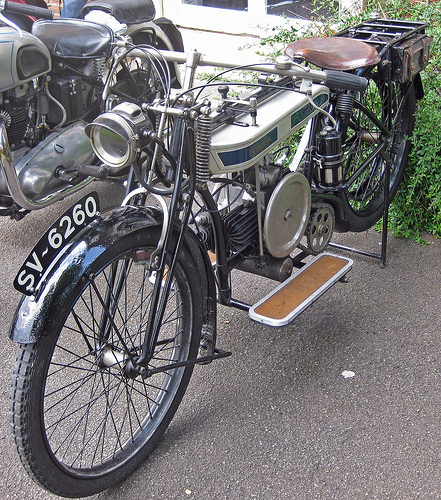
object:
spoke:
[100, 262, 140, 357]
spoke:
[47, 357, 120, 378]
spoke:
[122, 371, 136, 449]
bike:
[0, 0, 187, 223]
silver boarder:
[285, 315, 293, 324]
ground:
[0, 173, 441, 499]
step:
[245, 250, 354, 331]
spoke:
[96, 366, 112, 467]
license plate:
[11, 187, 102, 300]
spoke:
[96, 365, 116, 466]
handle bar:
[320, 66, 371, 91]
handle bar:
[100, 20, 135, 48]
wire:
[167, 78, 313, 112]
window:
[264, 1, 345, 30]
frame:
[87, 82, 249, 382]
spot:
[353, 16, 431, 30]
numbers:
[44, 223, 66, 252]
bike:
[7, 14, 432, 496]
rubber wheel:
[336, 47, 421, 235]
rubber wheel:
[6, 220, 215, 499]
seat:
[281, 34, 384, 75]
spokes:
[355, 142, 383, 216]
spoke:
[61, 320, 133, 361]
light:
[82, 109, 139, 170]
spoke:
[44, 375, 129, 433]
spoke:
[121, 251, 129, 350]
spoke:
[52, 340, 96, 367]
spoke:
[145, 328, 186, 370]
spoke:
[100, 363, 160, 409]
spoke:
[100, 269, 142, 360]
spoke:
[137, 262, 147, 360]